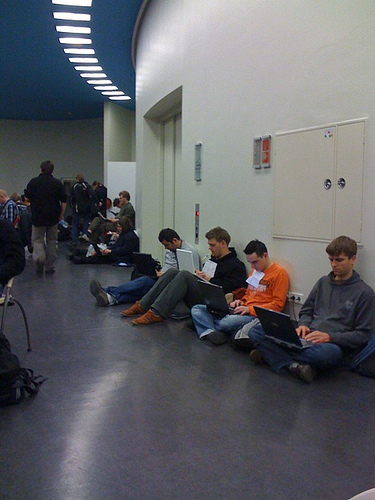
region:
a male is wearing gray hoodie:
[246, 224, 374, 385]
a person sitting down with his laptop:
[238, 216, 373, 384]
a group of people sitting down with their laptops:
[76, 210, 373, 390]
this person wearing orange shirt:
[189, 231, 294, 354]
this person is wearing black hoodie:
[117, 219, 250, 331]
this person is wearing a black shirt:
[16, 159, 78, 281]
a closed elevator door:
[124, 80, 197, 274]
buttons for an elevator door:
[180, 200, 213, 244]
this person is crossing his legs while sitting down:
[237, 231, 373, 382]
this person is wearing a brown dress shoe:
[116, 221, 254, 332]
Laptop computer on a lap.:
[248, 297, 318, 351]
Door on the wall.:
[267, 117, 370, 243]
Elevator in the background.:
[141, 81, 183, 274]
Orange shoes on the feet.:
[119, 296, 164, 329]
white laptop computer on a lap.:
[172, 248, 210, 286]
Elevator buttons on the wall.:
[191, 203, 202, 247]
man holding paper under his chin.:
[237, 239, 271, 293]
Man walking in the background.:
[21, 151, 69, 277]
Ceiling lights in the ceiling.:
[47, 0, 134, 108]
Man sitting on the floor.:
[250, 224, 373, 388]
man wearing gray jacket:
[280, 232, 370, 377]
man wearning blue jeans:
[289, 229, 353, 394]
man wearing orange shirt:
[242, 229, 285, 304]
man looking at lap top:
[304, 226, 359, 368]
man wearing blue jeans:
[246, 238, 283, 300]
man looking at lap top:
[241, 237, 286, 300]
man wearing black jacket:
[201, 223, 234, 276]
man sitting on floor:
[289, 227, 369, 362]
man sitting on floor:
[241, 230, 287, 299]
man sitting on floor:
[201, 228, 242, 274]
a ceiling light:
[51, 10, 91, 22]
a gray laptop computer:
[252, 303, 314, 347]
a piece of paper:
[244, 267, 263, 288]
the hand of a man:
[301, 327, 328, 344]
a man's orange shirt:
[241, 262, 290, 316]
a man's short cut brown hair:
[326, 234, 359, 263]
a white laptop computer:
[175, 247, 200, 276]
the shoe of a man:
[85, 278, 105, 297]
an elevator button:
[192, 208, 200, 218]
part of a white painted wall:
[133, 0, 359, 84]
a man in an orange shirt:
[188, 240, 289, 344]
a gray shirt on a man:
[297, 268, 371, 348]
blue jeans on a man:
[248, 322, 343, 372]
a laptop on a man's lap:
[253, 301, 320, 349]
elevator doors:
[159, 111, 182, 263]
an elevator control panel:
[191, 200, 201, 245]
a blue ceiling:
[0, 0, 142, 121]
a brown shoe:
[132, 306, 164, 324]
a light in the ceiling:
[51, 22, 92, 36]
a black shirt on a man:
[21, 173, 69, 226]